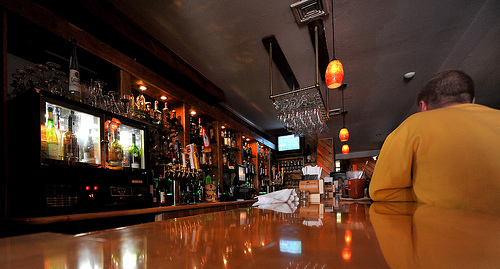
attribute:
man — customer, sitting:
[368, 68, 499, 209]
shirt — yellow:
[368, 105, 499, 212]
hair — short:
[417, 72, 476, 108]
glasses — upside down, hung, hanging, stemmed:
[276, 95, 331, 136]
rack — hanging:
[262, 18, 330, 125]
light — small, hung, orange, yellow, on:
[325, 60, 344, 90]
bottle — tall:
[66, 36, 82, 100]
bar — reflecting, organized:
[1, 194, 389, 269]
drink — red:
[347, 160, 368, 197]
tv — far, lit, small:
[275, 135, 302, 151]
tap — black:
[174, 140, 182, 164]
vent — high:
[290, 0, 330, 27]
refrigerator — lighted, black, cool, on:
[1, 87, 152, 217]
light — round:
[140, 85, 148, 92]